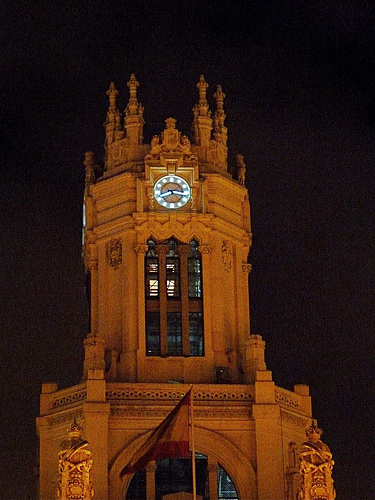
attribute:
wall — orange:
[89, 100, 290, 459]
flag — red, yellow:
[118, 391, 193, 475]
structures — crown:
[98, 71, 240, 160]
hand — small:
[169, 189, 185, 197]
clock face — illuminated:
[152, 172, 193, 210]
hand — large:
[156, 188, 174, 201]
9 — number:
[155, 183, 162, 194]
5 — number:
[175, 200, 183, 208]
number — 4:
[179, 196, 187, 206]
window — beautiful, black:
[142, 232, 205, 358]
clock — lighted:
[154, 157, 196, 212]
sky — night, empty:
[9, 0, 362, 489]